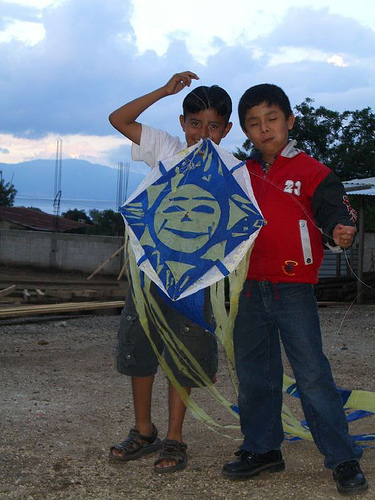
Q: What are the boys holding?
A: A kite.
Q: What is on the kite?
A: A smiling sun.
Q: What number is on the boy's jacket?
A: 23.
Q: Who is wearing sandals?
A: Boy on left.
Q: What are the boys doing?
A: Holding a kite.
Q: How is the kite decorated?
A: With a smiling face.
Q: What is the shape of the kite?
A: An octagon.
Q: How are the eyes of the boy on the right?
A: Closed.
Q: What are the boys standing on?
A: Gravel.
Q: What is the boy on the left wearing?
A: A t-shirt, shorts and sandals.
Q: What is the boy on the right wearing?
A: A jacket, blue jeans and dress shoes.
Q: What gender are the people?
A: Male.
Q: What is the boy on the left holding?
A: Kite.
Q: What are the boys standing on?
A: Gravel.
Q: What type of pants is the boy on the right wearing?
A: Jeans.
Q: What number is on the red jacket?
A: 23.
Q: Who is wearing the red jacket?
A: Boy on the right.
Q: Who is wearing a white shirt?
A: Boy on the left.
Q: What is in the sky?
A: Clouds.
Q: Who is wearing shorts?
A: Boy on the left.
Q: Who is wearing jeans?
A: Boy on the right.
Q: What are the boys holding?
A: A kite.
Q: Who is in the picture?
A: Two boys.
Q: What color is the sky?
A: Blue.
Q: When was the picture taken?
A: During the day.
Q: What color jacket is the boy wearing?
A: Red and black.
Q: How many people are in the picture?
A: Two.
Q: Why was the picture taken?
A: To capture the boys.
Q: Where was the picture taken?
A: Near boys.